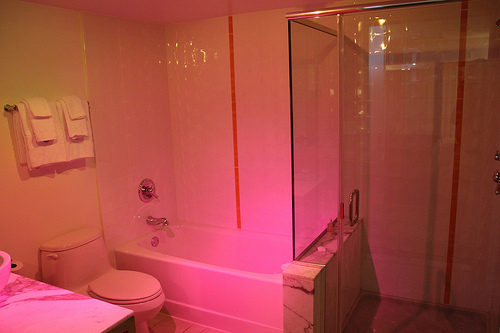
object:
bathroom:
[0, 0, 499, 333]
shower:
[91, 6, 294, 332]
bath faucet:
[146, 215, 170, 228]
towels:
[11, 95, 94, 172]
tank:
[38, 228, 112, 291]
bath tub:
[115, 225, 284, 332]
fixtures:
[136, 177, 159, 203]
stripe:
[436, 2, 475, 309]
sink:
[0, 250, 136, 332]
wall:
[267, 0, 499, 328]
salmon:
[0, 10, 84, 100]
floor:
[148, 310, 223, 331]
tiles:
[171, 68, 226, 130]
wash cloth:
[24, 97, 57, 144]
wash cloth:
[56, 94, 88, 141]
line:
[228, 13, 244, 229]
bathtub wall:
[166, 0, 291, 228]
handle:
[139, 177, 156, 202]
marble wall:
[281, 218, 383, 333]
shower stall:
[284, 1, 499, 331]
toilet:
[38, 226, 166, 333]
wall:
[0, 5, 93, 241]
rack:
[1, 98, 90, 112]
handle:
[47, 253, 59, 261]